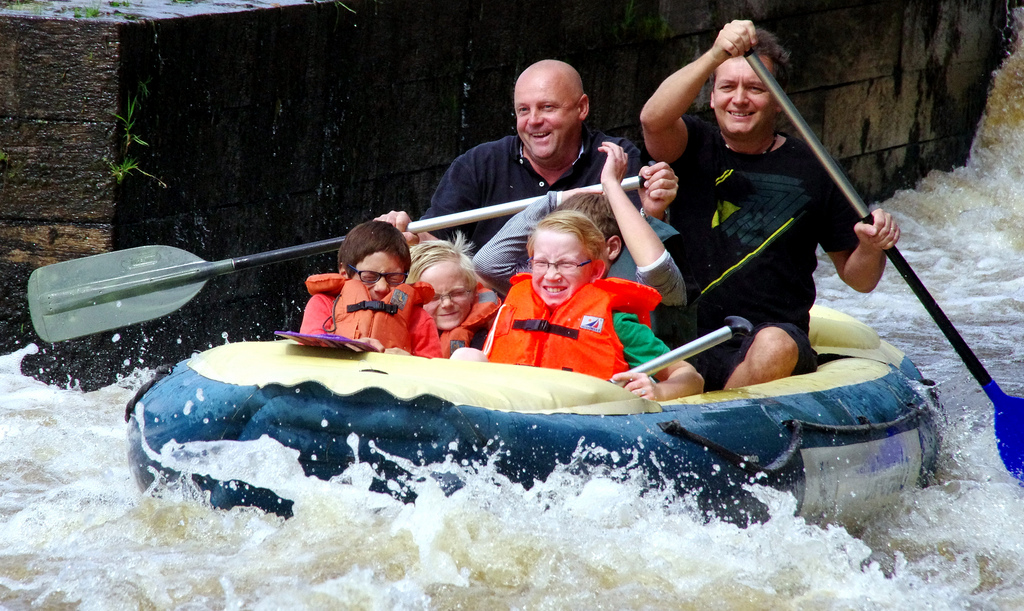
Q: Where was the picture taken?
A: In a river.